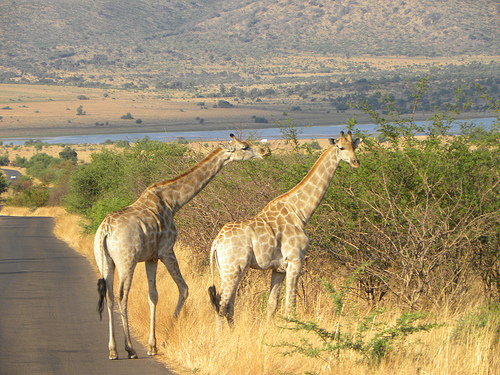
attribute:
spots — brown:
[274, 200, 302, 227]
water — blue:
[67, 120, 478, 147]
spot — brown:
[182, 185, 191, 194]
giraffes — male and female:
[93, 143, 367, 325]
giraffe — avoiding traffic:
[205, 130, 444, 347]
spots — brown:
[255, 207, 300, 239]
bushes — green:
[2, 141, 493, 371]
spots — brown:
[140, 198, 166, 226]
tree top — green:
[251, 151, 309, 187]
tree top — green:
[153, 146, 185, 157]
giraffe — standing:
[204, 126, 365, 340]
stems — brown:
[328, 173, 483, 303]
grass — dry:
[56, 237, 471, 373]